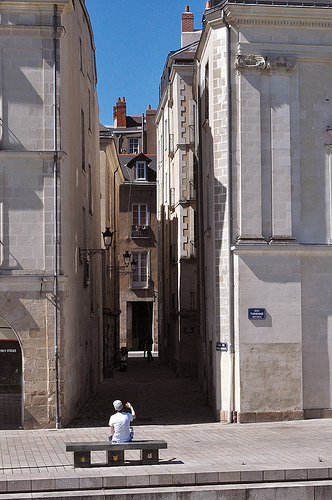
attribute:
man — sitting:
[110, 391, 136, 440]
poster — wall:
[244, 303, 278, 324]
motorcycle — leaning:
[117, 342, 130, 372]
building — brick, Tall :
[154, 2, 201, 375]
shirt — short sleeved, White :
[110, 414, 130, 438]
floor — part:
[144, 364, 188, 423]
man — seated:
[106, 395, 138, 445]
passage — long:
[80, 227, 209, 423]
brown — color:
[109, 167, 175, 429]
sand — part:
[139, 448, 161, 465]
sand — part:
[105, 450, 124, 466]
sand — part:
[73, 451, 91, 468]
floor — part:
[0, 417, 331, 480]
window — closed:
[132, 203, 148, 230]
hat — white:
[111, 399, 123, 409]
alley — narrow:
[78, 329, 208, 402]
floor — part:
[227, 439, 260, 451]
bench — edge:
[35, 405, 200, 478]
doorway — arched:
[125, 300, 157, 354]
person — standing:
[107, 398, 134, 437]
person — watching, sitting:
[108, 396, 139, 449]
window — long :
[136, 159, 146, 179]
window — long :
[129, 138, 139, 153]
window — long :
[132, 203, 150, 227]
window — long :
[130, 250, 148, 289]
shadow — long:
[256, 315, 274, 327]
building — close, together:
[16, 9, 97, 428]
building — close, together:
[197, 9, 325, 421]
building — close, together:
[148, 49, 207, 391]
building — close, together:
[96, 120, 129, 377]